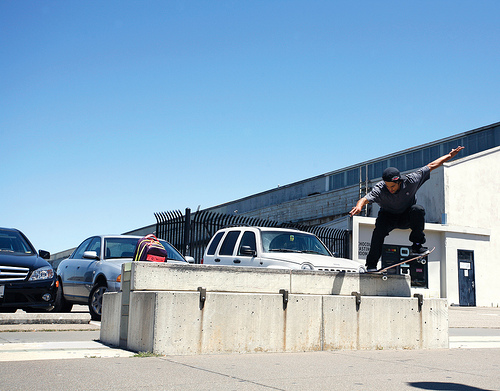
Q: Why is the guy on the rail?
A: Grinding.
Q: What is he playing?
A: Skateboarding.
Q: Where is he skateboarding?
A: On the rails.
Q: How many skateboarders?
A: 1.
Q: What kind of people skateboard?
A: Skateboarders.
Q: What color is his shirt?
A: Gray.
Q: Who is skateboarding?
A: The man.